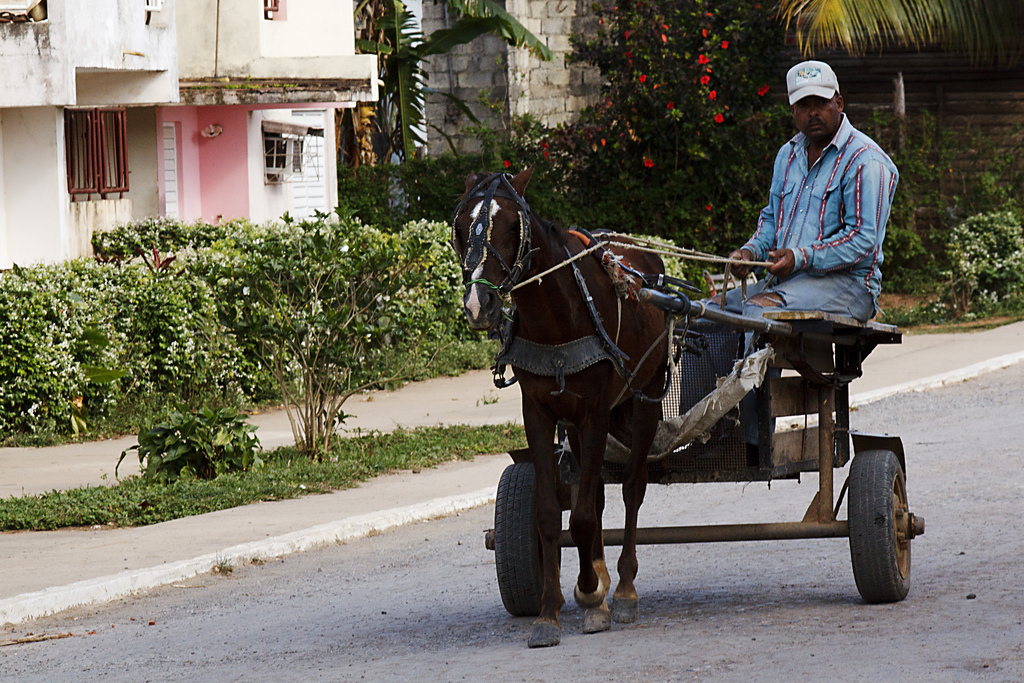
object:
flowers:
[714, 113, 723, 122]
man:
[706, 60, 898, 324]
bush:
[0, 218, 496, 448]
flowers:
[132, 337, 242, 381]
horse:
[454, 170, 669, 648]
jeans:
[695, 269, 876, 447]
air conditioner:
[262, 137, 305, 173]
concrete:
[0, 359, 1024, 683]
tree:
[354, 0, 552, 164]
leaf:
[403, 16, 513, 58]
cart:
[484, 281, 927, 617]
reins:
[566, 228, 642, 361]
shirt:
[740, 113, 899, 315]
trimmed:
[139, 407, 259, 476]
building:
[0, 0, 378, 267]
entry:
[156, 105, 247, 226]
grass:
[0, 422, 529, 537]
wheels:
[846, 449, 923, 605]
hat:
[786, 62, 841, 103]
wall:
[422, 0, 605, 150]